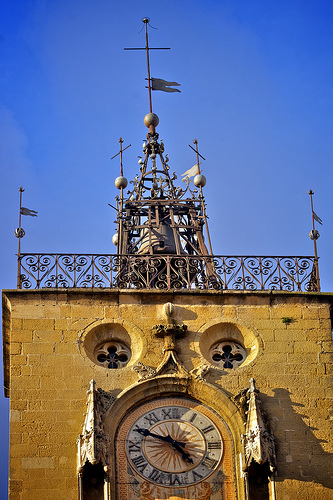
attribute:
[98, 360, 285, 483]
clock — white, circular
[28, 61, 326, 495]
building — old, tan, visibley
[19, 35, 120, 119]
sky — blur, blue, bright blue, clear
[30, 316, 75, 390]
stone — fancy, ornate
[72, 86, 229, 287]
tower — stone, old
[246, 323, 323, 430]
wall — brown, yellow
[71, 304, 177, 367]
window — circular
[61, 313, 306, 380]
brick — worn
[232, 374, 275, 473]
object — rectangular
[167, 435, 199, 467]
hand — hour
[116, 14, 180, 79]
cross — large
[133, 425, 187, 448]
hand — black, minutes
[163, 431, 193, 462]
hand — black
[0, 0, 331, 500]
sky — clear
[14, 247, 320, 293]
railing — black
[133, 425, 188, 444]
dial — black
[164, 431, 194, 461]
dial — black